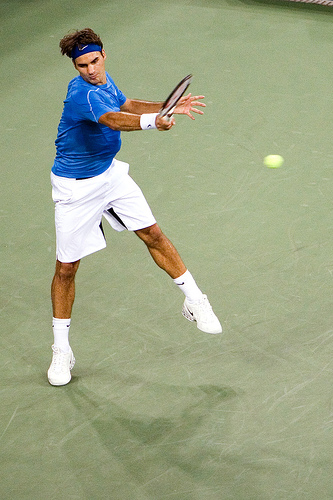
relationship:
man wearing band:
[46, 28, 223, 385] [68, 46, 102, 58]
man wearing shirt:
[46, 28, 223, 385] [51, 72, 126, 181]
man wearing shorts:
[46, 28, 223, 385] [51, 157, 157, 263]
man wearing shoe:
[46, 28, 223, 385] [46, 296, 223, 387]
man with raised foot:
[46, 28, 223, 385] [182, 295, 221, 334]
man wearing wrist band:
[46, 28, 223, 385] [139, 113, 156, 132]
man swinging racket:
[46, 28, 223, 385] [157, 73, 191, 122]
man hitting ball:
[46, 28, 223, 385] [266, 155, 284, 169]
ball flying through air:
[266, 155, 284, 169] [2, 1, 332, 500]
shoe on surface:
[45, 345, 75, 385] [1, 1, 332, 500]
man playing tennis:
[46, 28, 223, 385] [157, 74, 192, 122]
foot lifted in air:
[182, 295, 221, 334] [2, 1, 332, 500]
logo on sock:
[174, 281, 184, 287] [172, 268, 210, 300]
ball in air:
[266, 155, 284, 169] [2, 1, 332, 500]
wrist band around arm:
[139, 113, 156, 132] [74, 90, 171, 132]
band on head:
[68, 46, 102, 58] [59, 27, 104, 85]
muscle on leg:
[148, 246, 170, 271] [106, 179, 222, 335]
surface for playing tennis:
[1, 1, 332, 500] [157, 74, 192, 122]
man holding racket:
[46, 28, 223, 385] [157, 73, 191, 122]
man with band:
[46, 28, 223, 385] [68, 46, 102, 58]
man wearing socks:
[46, 28, 223, 385] [52, 268, 205, 344]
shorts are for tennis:
[51, 157, 157, 263] [157, 74, 192, 122]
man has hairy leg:
[46, 28, 223, 385] [106, 179, 222, 335]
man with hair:
[46, 28, 223, 385] [58, 28, 102, 58]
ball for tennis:
[266, 155, 284, 169] [157, 74, 192, 122]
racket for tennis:
[157, 73, 191, 122] [157, 74, 192, 122]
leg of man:
[106, 179, 222, 335] [46, 28, 223, 385]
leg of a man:
[106, 179, 222, 335] [46, 28, 223, 385]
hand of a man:
[175, 91, 206, 120] [46, 28, 223, 385]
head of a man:
[59, 27, 104, 85] [46, 28, 223, 385]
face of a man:
[72, 51, 104, 83] [46, 28, 223, 385]